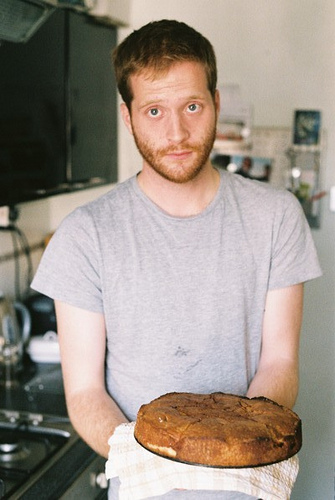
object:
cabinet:
[1, 1, 120, 205]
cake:
[144, 386, 307, 476]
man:
[26, 17, 328, 498]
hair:
[101, 16, 222, 98]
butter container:
[24, 333, 66, 367]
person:
[31, 19, 322, 498]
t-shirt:
[29, 169, 321, 498]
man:
[52, 20, 303, 497]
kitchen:
[1, 2, 334, 496]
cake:
[134, 392, 301, 465]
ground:
[243, 99, 255, 115]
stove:
[6, 321, 125, 494]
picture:
[281, 110, 324, 138]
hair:
[97, 15, 225, 107]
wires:
[3, 214, 34, 293]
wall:
[4, 1, 116, 293]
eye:
[185, 102, 204, 113]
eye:
[144, 104, 164, 118]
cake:
[126, 385, 311, 473]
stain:
[174, 343, 187, 359]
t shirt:
[30, 162, 324, 431]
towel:
[102, 421, 300, 498]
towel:
[79, 388, 326, 490]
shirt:
[32, 154, 328, 435]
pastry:
[128, 387, 306, 470]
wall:
[145, 49, 203, 84]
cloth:
[104, 419, 299, 497]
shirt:
[29, 166, 322, 422]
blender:
[0, 293, 33, 370]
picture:
[291, 105, 324, 146]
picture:
[224, 150, 277, 182]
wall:
[211, 3, 333, 195]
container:
[24, 329, 62, 362]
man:
[21, 21, 309, 479]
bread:
[142, 372, 333, 492]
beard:
[133, 124, 215, 185]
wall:
[224, 23, 332, 171]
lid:
[32, 328, 55, 345]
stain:
[172, 347, 190, 370]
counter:
[2, 264, 315, 383]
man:
[73, 166, 295, 363]